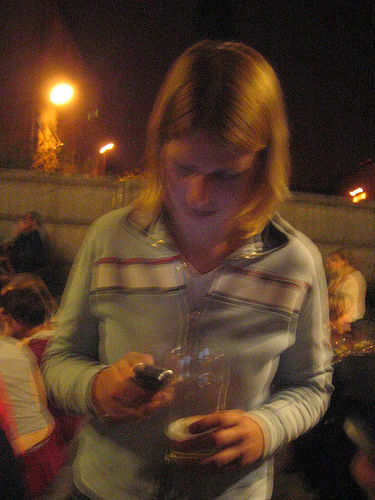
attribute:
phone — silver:
[134, 359, 173, 394]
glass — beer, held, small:
[162, 343, 230, 476]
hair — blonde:
[139, 36, 294, 241]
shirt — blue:
[45, 204, 337, 500]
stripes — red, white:
[88, 251, 186, 271]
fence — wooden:
[1, 166, 374, 290]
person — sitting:
[45, 37, 339, 498]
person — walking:
[325, 249, 370, 347]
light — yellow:
[45, 76, 82, 112]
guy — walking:
[8, 209, 51, 277]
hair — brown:
[3, 283, 48, 328]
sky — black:
[1, 0, 372, 204]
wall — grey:
[1, 169, 374, 298]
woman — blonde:
[43, 38, 337, 499]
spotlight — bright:
[43, 72, 82, 113]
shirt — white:
[325, 269, 366, 327]